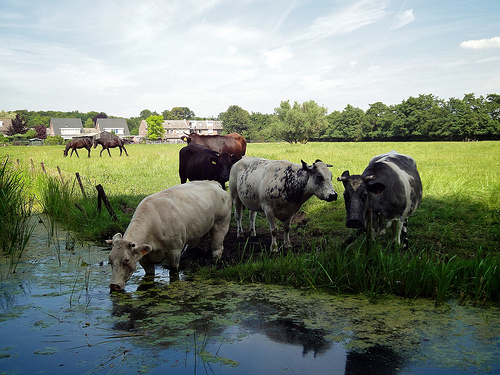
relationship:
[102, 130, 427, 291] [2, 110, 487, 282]
cows are on farm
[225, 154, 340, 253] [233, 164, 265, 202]
cow has black spots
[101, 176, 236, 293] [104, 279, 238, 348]
cow has reflection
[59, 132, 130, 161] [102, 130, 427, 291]
two horses are behind cows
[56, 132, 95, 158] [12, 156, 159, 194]
horse eating grass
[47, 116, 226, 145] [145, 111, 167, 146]
homes are in front of tree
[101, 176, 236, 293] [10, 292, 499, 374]
cow drinking water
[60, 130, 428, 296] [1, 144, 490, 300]
animals are in field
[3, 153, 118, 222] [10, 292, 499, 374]
fence next to water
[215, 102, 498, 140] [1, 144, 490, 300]
trees are at end of field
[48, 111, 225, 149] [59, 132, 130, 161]
buildings are behind two horses